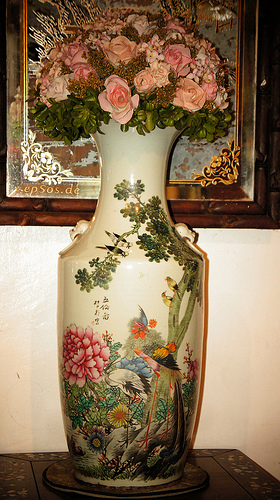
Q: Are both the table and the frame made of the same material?
A: Yes, both the table and the frame are made of wood.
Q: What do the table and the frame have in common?
A: The material, both the table and the frame are wooden.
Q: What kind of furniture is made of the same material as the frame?
A: The table is made of the same material as the frame.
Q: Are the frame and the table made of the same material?
A: Yes, both the frame and the table are made of wood.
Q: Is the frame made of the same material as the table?
A: Yes, both the frame and the table are made of wood.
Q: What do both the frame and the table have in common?
A: The material, both the frame and the table are wooden.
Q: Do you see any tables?
A: Yes, there is a table.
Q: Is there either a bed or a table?
A: Yes, there is a table.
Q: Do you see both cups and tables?
A: No, there is a table but no cups.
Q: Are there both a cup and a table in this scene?
A: No, there is a table but no cups.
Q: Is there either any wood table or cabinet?
A: Yes, there is a wood table.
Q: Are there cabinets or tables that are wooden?
A: Yes, the table is wooden.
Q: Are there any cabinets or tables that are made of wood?
A: Yes, the table is made of wood.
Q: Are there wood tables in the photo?
A: Yes, there is a wood table.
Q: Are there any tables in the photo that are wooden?
A: Yes, there is a table that is wooden.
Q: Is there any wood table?
A: Yes, there is a table that is made of wood.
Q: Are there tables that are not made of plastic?
A: Yes, there is a table that is made of wood.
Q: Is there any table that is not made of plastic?
A: Yes, there is a table that is made of wood.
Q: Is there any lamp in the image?
A: No, there are no lamps.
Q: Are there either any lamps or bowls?
A: No, there are no lamps or bowls.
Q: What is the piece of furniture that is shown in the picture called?
A: The piece of furniture is a table.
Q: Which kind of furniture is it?
A: The piece of furniture is a table.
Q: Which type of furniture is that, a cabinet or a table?
A: This is a table.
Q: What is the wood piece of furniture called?
A: The piece of furniture is a table.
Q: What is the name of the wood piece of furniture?
A: The piece of furniture is a table.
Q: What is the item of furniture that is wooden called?
A: The piece of furniture is a table.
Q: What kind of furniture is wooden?
A: The furniture is a table.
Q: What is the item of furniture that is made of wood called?
A: The piece of furniture is a table.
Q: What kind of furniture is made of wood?
A: The furniture is a table.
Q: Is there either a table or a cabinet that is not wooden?
A: No, there is a table but it is wooden.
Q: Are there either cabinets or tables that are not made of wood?
A: No, there is a table but it is made of wood.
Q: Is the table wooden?
A: Yes, the table is wooden.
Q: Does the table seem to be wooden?
A: Yes, the table is wooden.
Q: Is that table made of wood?
A: Yes, the table is made of wood.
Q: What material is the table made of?
A: The table is made of wood.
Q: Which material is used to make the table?
A: The table is made of wood.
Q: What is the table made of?
A: The table is made of wood.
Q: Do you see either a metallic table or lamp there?
A: No, there is a table but it is wooden.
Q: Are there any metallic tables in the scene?
A: No, there is a table but it is wooden.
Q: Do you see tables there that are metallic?
A: No, there is a table but it is wooden.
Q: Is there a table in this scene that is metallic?
A: No, there is a table but it is wooden.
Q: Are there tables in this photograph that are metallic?
A: No, there is a table but it is wooden.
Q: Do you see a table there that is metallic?
A: No, there is a table but it is wooden.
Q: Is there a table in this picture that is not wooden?
A: No, there is a table but it is wooden.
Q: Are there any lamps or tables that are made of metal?
A: No, there is a table but it is made of wood.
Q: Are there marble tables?
A: No, there is a table but it is made of wood.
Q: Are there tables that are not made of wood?
A: No, there is a table but it is made of wood.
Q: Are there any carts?
A: No, there are no carts.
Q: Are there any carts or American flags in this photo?
A: No, there are no carts or American flags.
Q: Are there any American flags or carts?
A: No, there are no carts or American flags.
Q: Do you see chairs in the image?
A: No, there are no chairs.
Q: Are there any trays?
A: No, there are no trays.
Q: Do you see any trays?
A: No, there are no trays.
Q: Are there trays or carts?
A: No, there are no trays or carts.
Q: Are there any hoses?
A: No, there are no hoses.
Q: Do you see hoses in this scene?
A: No, there are no hoses.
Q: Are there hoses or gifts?
A: No, there are no hoses or gifts.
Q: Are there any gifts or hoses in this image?
A: No, there are no hoses or gifts.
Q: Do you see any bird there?
A: Yes, there is a bird.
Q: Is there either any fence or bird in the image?
A: Yes, there is a bird.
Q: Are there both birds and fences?
A: No, there is a bird but no fences.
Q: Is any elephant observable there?
A: No, there are no elephants.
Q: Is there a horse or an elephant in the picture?
A: No, there are no elephants or horses.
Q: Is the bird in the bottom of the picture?
A: Yes, the bird is in the bottom of the image.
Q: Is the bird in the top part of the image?
A: No, the bird is in the bottom of the image.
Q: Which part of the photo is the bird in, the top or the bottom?
A: The bird is in the bottom of the image.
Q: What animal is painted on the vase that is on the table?
A: The bird is painted on the vase.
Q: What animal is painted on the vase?
A: The bird is painted on the vase.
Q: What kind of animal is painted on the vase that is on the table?
A: The animal is a bird.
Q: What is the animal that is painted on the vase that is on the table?
A: The animal is a bird.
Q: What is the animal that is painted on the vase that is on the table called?
A: The animal is a bird.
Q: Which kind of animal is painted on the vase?
A: The animal is a bird.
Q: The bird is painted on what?
A: The bird is painted on the vase.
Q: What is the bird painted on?
A: The bird is painted on the vase.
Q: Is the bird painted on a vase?
A: Yes, the bird is painted on a vase.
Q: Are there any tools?
A: No, there are no tools.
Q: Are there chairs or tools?
A: No, there are no tools or chairs.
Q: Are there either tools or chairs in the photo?
A: No, there are no tools or chairs.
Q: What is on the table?
A: The vase is on the table.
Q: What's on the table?
A: The vase is on the table.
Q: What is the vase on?
A: The vase is on the table.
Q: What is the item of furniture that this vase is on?
A: The piece of furniture is a table.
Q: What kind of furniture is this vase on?
A: The vase is on the table.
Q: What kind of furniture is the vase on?
A: The vase is on the table.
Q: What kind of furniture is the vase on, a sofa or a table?
A: The vase is on a table.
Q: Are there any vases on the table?
A: Yes, there is a vase on the table.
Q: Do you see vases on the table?
A: Yes, there is a vase on the table.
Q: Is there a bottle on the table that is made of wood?
A: No, there is a vase on the table.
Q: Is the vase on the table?
A: Yes, the vase is on the table.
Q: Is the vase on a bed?
A: No, the vase is on the table.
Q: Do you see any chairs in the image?
A: No, there are no chairs.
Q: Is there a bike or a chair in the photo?
A: No, there are no chairs or bikes.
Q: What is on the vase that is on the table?
A: The flower is on the vase.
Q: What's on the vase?
A: The flower is on the vase.